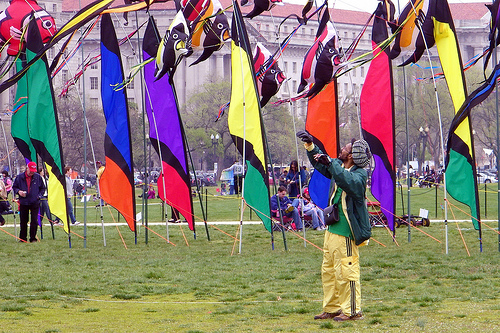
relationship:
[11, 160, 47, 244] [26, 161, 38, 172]
man with baseball cap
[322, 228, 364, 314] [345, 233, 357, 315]
pants with stripes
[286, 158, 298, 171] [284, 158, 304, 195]
head on woman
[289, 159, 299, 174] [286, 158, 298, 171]
dark hair on head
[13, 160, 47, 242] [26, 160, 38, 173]
man wearing baseball cap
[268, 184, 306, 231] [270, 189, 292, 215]
person sitting coat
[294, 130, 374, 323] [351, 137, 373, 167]
man has hat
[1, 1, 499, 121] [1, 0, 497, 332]
building in background of event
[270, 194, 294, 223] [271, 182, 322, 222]
person sits on bench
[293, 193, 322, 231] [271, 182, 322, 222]
person sits on bench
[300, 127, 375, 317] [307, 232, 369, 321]
man wears pants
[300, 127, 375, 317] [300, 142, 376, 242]
man wears shirt